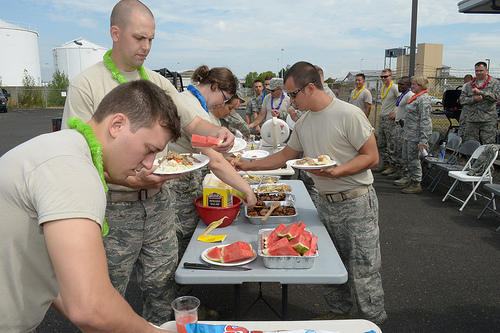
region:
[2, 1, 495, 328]
Army personnel gathered to eat a potluck meal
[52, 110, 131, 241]
A green lei around the man's neck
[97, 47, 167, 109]
A ring of green flowers on the bald man's neck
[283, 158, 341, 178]
A white paper plate in the man's hand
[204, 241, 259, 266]
Large chunks of watermelon on the white plate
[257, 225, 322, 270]
A silver tray full of watermelon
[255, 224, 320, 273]
An aluminum baking tray with food in it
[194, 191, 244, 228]
A large red bowl on the white table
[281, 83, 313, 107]
Small black glasses on the man's face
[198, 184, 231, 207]
A small yellow box in the large red bowl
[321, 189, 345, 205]
the buckle on the belt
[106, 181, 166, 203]
the tan belt on the man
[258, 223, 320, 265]
the foil pan of watermelon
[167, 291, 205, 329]
the plastic cup on the table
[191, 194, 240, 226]
the red bowl on the table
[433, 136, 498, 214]
the chairs on the pavement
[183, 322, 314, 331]
the chips on the table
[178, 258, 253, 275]
the knife on the folding table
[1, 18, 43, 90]
the white water tank behind the fence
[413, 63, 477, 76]
the barb wire on top of the fence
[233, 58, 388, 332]
man wearing camouflage pants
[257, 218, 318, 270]
tray has watermelon slices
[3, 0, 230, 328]
two men wearing green leis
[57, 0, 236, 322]
man holding a watermelon slice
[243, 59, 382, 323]
man holding a plate of food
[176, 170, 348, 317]
trays of food on top of table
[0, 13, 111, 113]
two white silos in background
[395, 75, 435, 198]
woman wearing army fatigues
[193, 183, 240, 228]
table has red bowl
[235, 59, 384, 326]
man wearing black sunglasses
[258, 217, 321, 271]
tray of watermellon slices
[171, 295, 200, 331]
pastic cup with pink juice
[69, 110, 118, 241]
lime green party lei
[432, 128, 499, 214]
row of fold out chairs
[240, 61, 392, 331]
man in shades serving himself food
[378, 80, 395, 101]
yellow party lei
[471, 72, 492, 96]
red party lei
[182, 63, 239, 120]
blue party lei on woman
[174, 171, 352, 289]
folding table filled with food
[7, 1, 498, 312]
military men and woman at gathering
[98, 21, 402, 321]
military members getting food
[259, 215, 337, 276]
watermelon cut up in a container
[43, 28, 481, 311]
military troops getting food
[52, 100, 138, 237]
a green lei around a soldier's neck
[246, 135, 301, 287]
a table laid out with food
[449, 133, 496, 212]
metal folding chairs for the troops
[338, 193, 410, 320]
camouflage pants that military wear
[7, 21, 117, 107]
two white silos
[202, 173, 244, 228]
a condiment in a red tub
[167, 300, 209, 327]
a drinking cup with red liquid in it